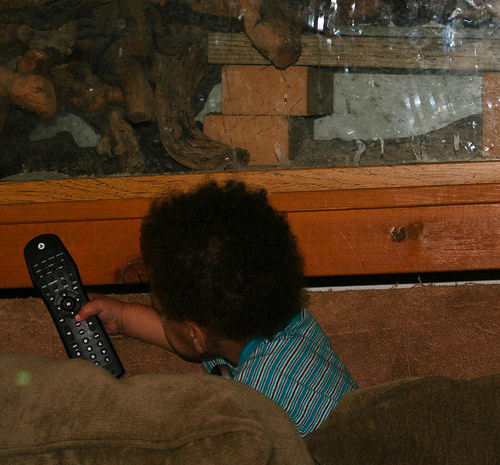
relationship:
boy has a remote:
[72, 171, 371, 442] [12, 230, 139, 382]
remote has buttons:
[12, 230, 139, 382] [33, 257, 109, 373]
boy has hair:
[72, 171, 371, 442] [136, 168, 316, 340]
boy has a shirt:
[72, 171, 371, 442] [217, 294, 367, 436]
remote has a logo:
[12, 230, 139, 382] [33, 238, 51, 251]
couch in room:
[9, 341, 499, 459] [1, 6, 498, 463]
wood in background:
[6, 7, 493, 272] [0, 1, 492, 296]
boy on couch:
[72, 171, 371, 442] [9, 341, 499, 459]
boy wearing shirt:
[72, 171, 371, 442] [217, 294, 367, 436]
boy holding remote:
[72, 171, 371, 442] [12, 230, 139, 382]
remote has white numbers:
[12, 230, 139, 382] [66, 334, 120, 368]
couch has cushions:
[9, 341, 499, 459] [4, 345, 332, 464]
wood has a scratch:
[6, 7, 493, 272] [326, 221, 369, 273]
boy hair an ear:
[72, 171, 371, 442] [168, 314, 209, 357]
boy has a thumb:
[72, 171, 371, 442] [69, 298, 108, 323]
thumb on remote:
[69, 298, 108, 323] [12, 230, 139, 382]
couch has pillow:
[9, 341, 499, 459] [0, 353, 319, 465]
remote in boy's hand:
[12, 230, 139, 382] [68, 288, 122, 342]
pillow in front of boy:
[0, 350, 318, 464] [72, 171, 371, 442]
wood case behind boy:
[0, 142, 499, 282] [72, 171, 371, 442]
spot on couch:
[0, 364, 45, 396] [9, 341, 499, 459]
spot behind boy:
[0, 364, 45, 396] [72, 171, 371, 442]